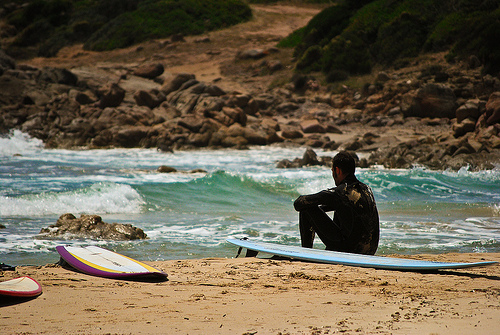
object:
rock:
[36, 212, 148, 240]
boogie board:
[55, 243, 171, 281]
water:
[0, 134, 499, 255]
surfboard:
[223, 232, 498, 270]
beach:
[3, 256, 499, 334]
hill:
[0, 0, 500, 161]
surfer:
[294, 150, 379, 253]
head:
[331, 150, 357, 186]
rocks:
[98, 82, 129, 108]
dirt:
[137, 32, 213, 57]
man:
[294, 150, 378, 252]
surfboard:
[0, 274, 42, 298]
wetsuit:
[295, 176, 380, 256]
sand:
[342, 188, 363, 205]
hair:
[333, 150, 360, 172]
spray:
[1, 125, 46, 156]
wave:
[0, 179, 155, 223]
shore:
[2, 252, 499, 333]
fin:
[233, 246, 243, 257]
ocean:
[0, 129, 499, 267]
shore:
[1, 1, 499, 171]